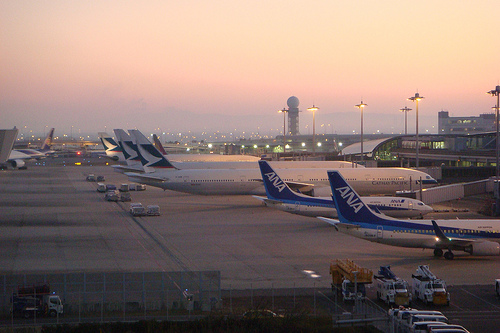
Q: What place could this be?
A: It is an airport.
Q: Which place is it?
A: It is an airport.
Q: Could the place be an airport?
A: Yes, it is an airport.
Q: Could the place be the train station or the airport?
A: It is the airport.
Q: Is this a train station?
A: No, it is an airport.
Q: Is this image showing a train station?
A: No, the picture is showing an airport.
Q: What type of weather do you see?
A: It is cloudy.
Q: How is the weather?
A: It is cloudy.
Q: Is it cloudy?
A: Yes, it is cloudy.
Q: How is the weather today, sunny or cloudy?
A: It is cloudy.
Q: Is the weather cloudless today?
A: No, it is cloudy.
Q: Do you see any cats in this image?
A: No, there are no cats.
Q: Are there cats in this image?
A: No, there are no cats.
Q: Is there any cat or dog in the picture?
A: No, there are no cats or dogs.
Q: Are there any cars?
A: No, there are no cars.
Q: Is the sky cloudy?
A: Yes, the sky is cloudy.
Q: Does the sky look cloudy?
A: Yes, the sky is cloudy.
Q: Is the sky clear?
A: No, the sky is cloudy.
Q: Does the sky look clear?
A: No, the sky is cloudy.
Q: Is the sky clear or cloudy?
A: The sky is cloudy.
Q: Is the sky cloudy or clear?
A: The sky is cloudy.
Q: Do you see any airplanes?
A: Yes, there is an airplane.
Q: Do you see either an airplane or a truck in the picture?
A: Yes, there is an airplane.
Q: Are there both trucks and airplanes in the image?
A: Yes, there are both an airplane and a truck.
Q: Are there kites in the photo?
A: No, there are no kites.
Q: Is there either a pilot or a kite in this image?
A: No, there are no kites or pilots.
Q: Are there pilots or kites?
A: No, there are no kites or pilots.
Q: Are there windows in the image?
A: Yes, there are windows.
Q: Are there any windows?
A: Yes, there are windows.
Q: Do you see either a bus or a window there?
A: Yes, there are windows.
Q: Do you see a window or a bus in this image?
A: Yes, there are windows.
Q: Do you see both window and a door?
A: No, there are windows but no doors.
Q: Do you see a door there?
A: No, there are no doors.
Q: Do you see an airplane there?
A: Yes, there is an airplane.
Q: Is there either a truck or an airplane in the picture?
A: Yes, there is an airplane.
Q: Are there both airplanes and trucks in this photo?
A: Yes, there are both an airplane and a truck.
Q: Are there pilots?
A: No, there are no pilots.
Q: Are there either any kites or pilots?
A: No, there are no pilots or kites.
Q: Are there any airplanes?
A: Yes, there is an airplane.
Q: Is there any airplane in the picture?
A: Yes, there is an airplane.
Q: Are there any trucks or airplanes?
A: Yes, there is an airplane.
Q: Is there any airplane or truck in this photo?
A: Yes, there is an airplane.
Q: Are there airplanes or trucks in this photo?
A: Yes, there is an airplane.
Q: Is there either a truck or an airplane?
A: Yes, there is an airplane.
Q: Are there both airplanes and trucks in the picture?
A: Yes, there are both an airplane and a truck.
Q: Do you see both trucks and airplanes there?
A: Yes, there are both an airplane and a truck.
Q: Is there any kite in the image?
A: No, there are no kites.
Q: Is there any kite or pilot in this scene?
A: No, there are no kites or pilots.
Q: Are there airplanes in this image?
A: Yes, there is an airplane.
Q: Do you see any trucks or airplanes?
A: Yes, there is an airplane.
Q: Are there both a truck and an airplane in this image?
A: Yes, there are both an airplane and a truck.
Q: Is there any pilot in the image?
A: No, there are no pilots.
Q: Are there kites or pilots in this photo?
A: No, there are no pilots or kites.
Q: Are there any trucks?
A: Yes, there is a truck.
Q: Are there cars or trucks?
A: Yes, there is a truck.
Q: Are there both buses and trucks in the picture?
A: No, there is a truck but no buses.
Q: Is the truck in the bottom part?
A: Yes, the truck is in the bottom of the image.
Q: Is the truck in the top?
A: No, the truck is in the bottom of the image.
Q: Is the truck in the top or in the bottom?
A: The truck is in the bottom of the image.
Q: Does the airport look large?
A: Yes, the airport is large.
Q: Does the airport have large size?
A: Yes, the airport is large.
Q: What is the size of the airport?
A: The airport is large.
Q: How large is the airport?
A: The airport is large.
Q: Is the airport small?
A: No, the airport is large.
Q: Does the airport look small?
A: No, the airport is large.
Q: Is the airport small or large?
A: The airport is large.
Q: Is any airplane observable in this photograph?
A: Yes, there are airplanes.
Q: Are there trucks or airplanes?
A: Yes, there are airplanes.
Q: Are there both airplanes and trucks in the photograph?
A: Yes, there are both airplanes and a truck.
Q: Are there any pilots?
A: No, there are no pilots.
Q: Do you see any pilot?
A: No, there are no pilots.